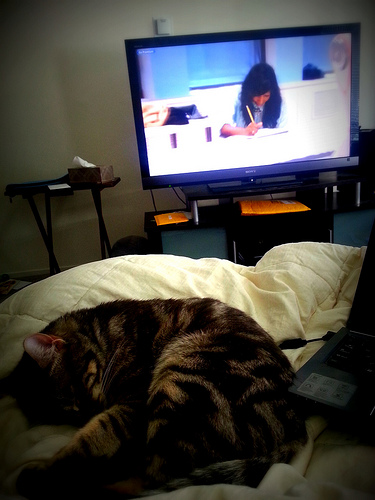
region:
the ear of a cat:
[21, 328, 62, 367]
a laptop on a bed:
[285, 208, 373, 437]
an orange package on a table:
[149, 210, 190, 225]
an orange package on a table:
[228, 194, 312, 217]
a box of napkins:
[60, 156, 115, 184]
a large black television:
[124, 22, 359, 190]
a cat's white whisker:
[89, 334, 135, 398]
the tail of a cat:
[129, 444, 306, 499]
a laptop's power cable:
[269, 321, 341, 352]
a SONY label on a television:
[242, 167, 258, 175]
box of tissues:
[66, 154, 114, 183]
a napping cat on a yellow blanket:
[11, 297, 297, 495]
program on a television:
[120, 21, 360, 186]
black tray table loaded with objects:
[6, 174, 120, 271]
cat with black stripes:
[10, 294, 308, 494]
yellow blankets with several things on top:
[0, 240, 370, 495]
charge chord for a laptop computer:
[272, 327, 333, 345]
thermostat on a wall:
[150, 15, 172, 36]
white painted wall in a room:
[0, 0, 371, 272]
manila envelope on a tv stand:
[236, 197, 308, 213]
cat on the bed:
[14, 293, 258, 421]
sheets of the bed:
[207, 271, 337, 313]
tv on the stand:
[129, 2, 360, 180]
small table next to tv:
[0, 146, 118, 208]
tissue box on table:
[67, 157, 100, 187]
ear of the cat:
[10, 324, 71, 359]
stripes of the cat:
[147, 313, 222, 409]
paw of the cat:
[45, 414, 107, 455]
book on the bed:
[283, 363, 370, 416]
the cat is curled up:
[21, 316, 143, 439]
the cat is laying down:
[159, 286, 216, 318]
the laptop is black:
[317, 350, 325, 367]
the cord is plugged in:
[319, 329, 339, 345]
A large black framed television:
[118, 7, 366, 195]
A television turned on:
[119, 31, 360, 190]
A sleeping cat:
[7, 287, 313, 499]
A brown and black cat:
[6, 294, 314, 490]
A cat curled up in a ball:
[8, 280, 304, 495]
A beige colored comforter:
[9, 243, 371, 499]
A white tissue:
[67, 152, 97, 171]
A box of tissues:
[65, 156, 115, 181]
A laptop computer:
[285, 206, 371, 430]